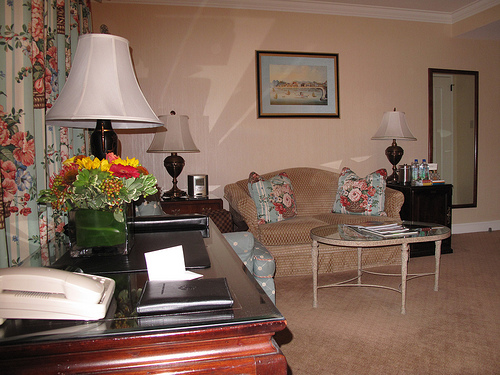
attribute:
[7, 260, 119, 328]
base — white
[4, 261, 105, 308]
receiver — white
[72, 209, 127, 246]
vase — green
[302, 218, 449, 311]
coffee table — oval-shaped, beige, glass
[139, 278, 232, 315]
paper book — shiny black leather